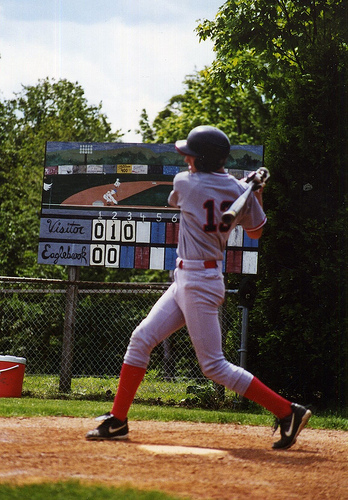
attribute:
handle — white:
[1, 361, 21, 378]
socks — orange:
[100, 363, 292, 426]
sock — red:
[239, 372, 295, 421]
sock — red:
[106, 358, 149, 422]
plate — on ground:
[139, 442, 228, 454]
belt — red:
[174, 256, 224, 270]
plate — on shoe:
[152, 428, 221, 473]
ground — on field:
[291, 110, 303, 119]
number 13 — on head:
[197, 195, 236, 231]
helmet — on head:
[165, 119, 240, 170]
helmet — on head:
[175, 118, 230, 175]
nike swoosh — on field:
[281, 411, 296, 436]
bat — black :
[235, 167, 260, 214]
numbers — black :
[91, 220, 138, 269]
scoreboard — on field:
[45, 140, 259, 275]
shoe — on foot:
[270, 396, 311, 451]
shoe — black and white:
[269, 398, 316, 455]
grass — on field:
[7, 393, 92, 419]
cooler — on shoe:
[5, 350, 28, 398]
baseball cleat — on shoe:
[270, 402, 311, 449]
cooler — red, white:
[0, 351, 29, 400]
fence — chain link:
[0, 274, 249, 393]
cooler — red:
[0, 353, 27, 397]